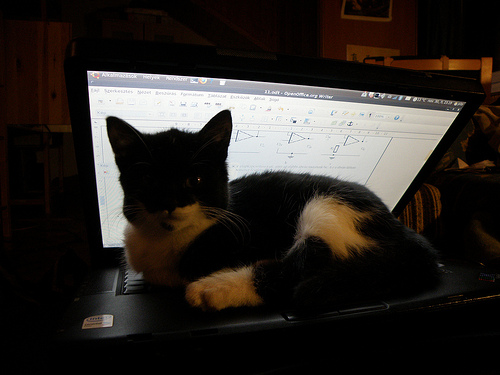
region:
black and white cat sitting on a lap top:
[104, 114, 443, 314]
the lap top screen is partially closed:
[67, 57, 489, 259]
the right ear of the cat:
[100, 113, 140, 170]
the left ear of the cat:
[200, 102, 235, 159]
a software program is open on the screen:
[100, 120, 400, 224]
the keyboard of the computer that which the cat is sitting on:
[74, 243, 496, 345]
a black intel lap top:
[57, 65, 486, 340]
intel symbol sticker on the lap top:
[77, 309, 119, 335]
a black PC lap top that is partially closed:
[47, 27, 489, 346]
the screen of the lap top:
[82, 64, 468, 256]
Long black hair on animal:
[250, 264, 277, 293]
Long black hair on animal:
[271, 249, 292, 276]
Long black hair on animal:
[291, 255, 340, 300]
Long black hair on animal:
[332, 263, 384, 305]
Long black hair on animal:
[382, 236, 430, 280]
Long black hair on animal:
[351, 183, 397, 263]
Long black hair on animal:
[329, 170, 369, 203]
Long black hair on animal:
[292, 156, 323, 201]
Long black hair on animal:
[257, 168, 315, 213]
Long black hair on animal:
[222, 225, 295, 259]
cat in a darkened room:
[36, 17, 488, 362]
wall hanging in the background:
[325, 0, 406, 30]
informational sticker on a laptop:
[80, 306, 117, 331]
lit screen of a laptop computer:
[246, 82, 392, 164]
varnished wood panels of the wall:
[2, 21, 62, 116]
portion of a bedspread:
[406, 187, 436, 224]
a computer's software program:
[240, 91, 415, 171]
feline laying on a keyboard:
[44, 109, 471, 348]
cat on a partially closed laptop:
[45, 15, 481, 360]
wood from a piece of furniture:
[385, 52, 495, 82]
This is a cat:
[82, 98, 452, 324]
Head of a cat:
[96, 101, 242, 256]